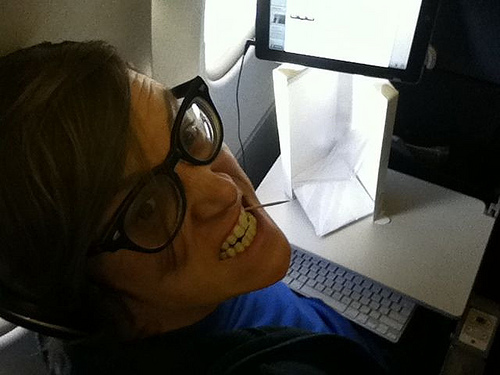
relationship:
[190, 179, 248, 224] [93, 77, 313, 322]
nose of face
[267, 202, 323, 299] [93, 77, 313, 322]
chin of face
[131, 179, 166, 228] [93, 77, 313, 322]
eye on face